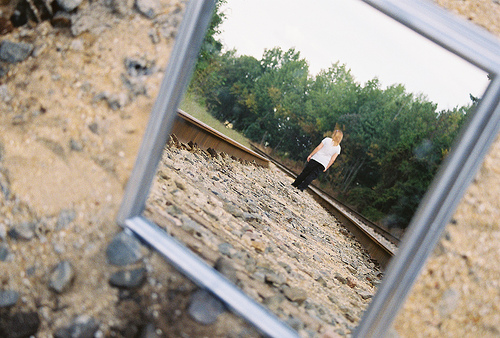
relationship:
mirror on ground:
[164, 9, 476, 314] [0, 78, 82, 223]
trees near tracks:
[208, 52, 475, 217] [165, 104, 402, 260]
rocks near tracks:
[229, 131, 366, 318] [165, 104, 402, 260]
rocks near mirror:
[73, 257, 206, 337] [164, 9, 476, 314]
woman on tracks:
[291, 125, 353, 196] [165, 104, 402, 260]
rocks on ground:
[229, 131, 366, 318] [0, 78, 82, 223]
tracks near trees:
[165, 104, 402, 260] [208, 52, 475, 217]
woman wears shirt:
[291, 125, 353, 196] [321, 130, 349, 165]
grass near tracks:
[181, 92, 245, 144] [165, 104, 402, 260]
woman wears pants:
[291, 125, 353, 196] [298, 147, 323, 196]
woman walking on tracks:
[291, 125, 353, 196] [165, 104, 402, 260]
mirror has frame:
[164, 9, 476, 314] [79, 7, 237, 253]